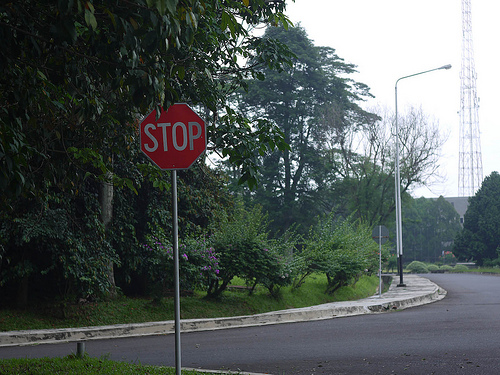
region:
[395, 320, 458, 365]
Road is grey color.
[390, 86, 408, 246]
poles are grey color.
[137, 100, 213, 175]
sign board is red and white color.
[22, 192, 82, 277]
trees are green color.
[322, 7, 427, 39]
Sky is white color.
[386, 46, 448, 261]
Two lamp post is seen.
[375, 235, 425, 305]
lamp post is in side walk.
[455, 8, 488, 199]
one tower is seen.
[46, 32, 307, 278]
Trees are seen in the sides of the road.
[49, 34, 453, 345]
Day time picture.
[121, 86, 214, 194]
the sign is red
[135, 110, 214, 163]
the sign says stop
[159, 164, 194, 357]
the pole is gray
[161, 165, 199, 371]
the pole is metal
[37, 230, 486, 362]
the street is gray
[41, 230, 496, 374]
the street is long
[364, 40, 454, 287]
the light is tall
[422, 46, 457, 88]
the light is off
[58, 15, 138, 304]
the trees are green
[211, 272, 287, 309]
the grass is green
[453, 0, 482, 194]
Tall tower in the background.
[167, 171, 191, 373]
Silver pole the stop sign is mounted on.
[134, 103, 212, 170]
The red stop sign.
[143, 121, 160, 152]
The letter S on the stop sign.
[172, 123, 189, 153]
The letter O on the stop sign.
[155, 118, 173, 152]
The letter T on the stop sign.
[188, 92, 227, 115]
The letter P on the stop sign.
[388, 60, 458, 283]
The light pole near the curve of the street.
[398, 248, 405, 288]
The black paint on the light pole.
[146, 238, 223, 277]
Purple flowers on the bush behind the stop sign.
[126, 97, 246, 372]
A sign is on the street.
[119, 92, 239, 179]
The sign says stop.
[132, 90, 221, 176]
The sign is red.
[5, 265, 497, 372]
The street is empty.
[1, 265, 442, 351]
A sidewalk lines the street.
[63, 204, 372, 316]
Bushes line the street.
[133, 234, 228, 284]
Purple flowers grow on the bush.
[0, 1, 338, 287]
Trees line the street.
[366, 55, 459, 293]
Street lights are on the sidewalk.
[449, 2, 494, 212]
A tower is in the background.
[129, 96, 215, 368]
a red stop sign on a silver pole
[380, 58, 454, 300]
a tall street light pole on the side of the road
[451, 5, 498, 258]
a large metal radio tower in the distance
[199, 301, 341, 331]
a dirty cement curb on the side of the road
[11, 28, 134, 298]
lush green trees and shrubs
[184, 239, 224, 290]
a bush with purple flowers next to the road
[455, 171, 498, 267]
a green pine tree in the distance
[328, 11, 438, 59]
a very cloudy white sky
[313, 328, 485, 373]
a paved road curving off into the distance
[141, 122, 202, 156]
the white lettering on the stop sign